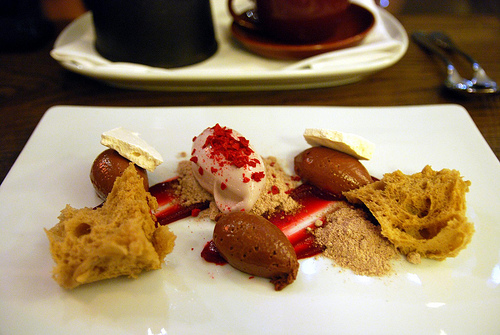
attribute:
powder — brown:
[309, 203, 399, 276]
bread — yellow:
[42, 159, 177, 291]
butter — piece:
[101, 129, 163, 174]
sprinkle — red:
[206, 125, 258, 173]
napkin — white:
[51, 39, 115, 76]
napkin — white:
[291, 36, 403, 76]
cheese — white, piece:
[216, 169, 261, 206]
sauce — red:
[151, 163, 358, 274]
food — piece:
[206, 202, 303, 289]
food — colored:
[44, 126, 476, 290]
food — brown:
[38, 152, 152, 295]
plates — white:
[63, 35, 413, 150]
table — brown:
[449, 15, 486, 36]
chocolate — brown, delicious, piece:
[207, 201, 307, 281]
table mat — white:
[84, 121, 408, 288]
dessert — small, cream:
[187, 125, 271, 211]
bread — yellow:
[344, 167, 476, 262]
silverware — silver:
[407, 23, 483, 100]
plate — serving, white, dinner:
[1, 100, 470, 331]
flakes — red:
[190, 122, 265, 186]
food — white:
[187, 123, 266, 207]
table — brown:
[2, 0, 484, 179]